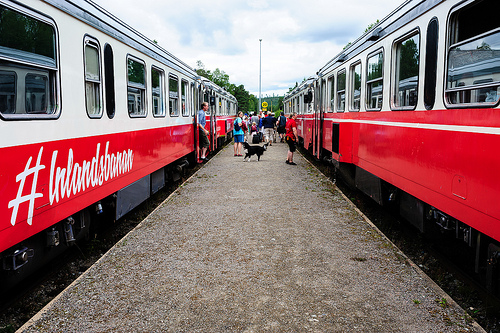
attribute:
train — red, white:
[1, 0, 247, 300]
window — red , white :
[3, 9, 68, 128]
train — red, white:
[7, 14, 233, 321]